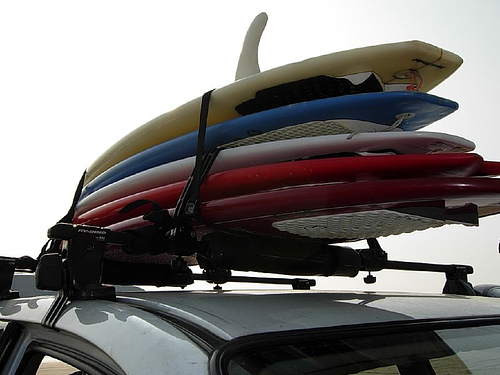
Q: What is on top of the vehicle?
A: Surfboards.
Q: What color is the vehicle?
A: Silver.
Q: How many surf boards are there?
A: Five.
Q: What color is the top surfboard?
A: Tan.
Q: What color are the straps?
A: Black.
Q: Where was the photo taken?
A: Above a car.